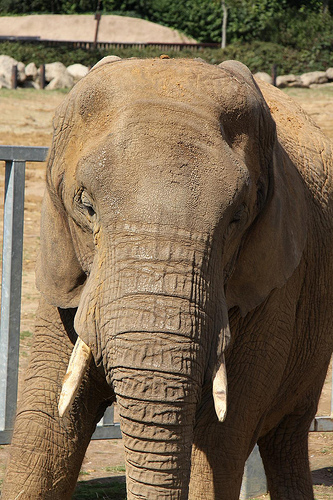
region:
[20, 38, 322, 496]
this is an elephant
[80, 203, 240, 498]
trunk of the elephant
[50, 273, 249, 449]
the elephant has tusks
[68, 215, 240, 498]
wrinkles on elephant trunk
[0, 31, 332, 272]
dirt on the elephant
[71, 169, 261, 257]
eyes on the elephant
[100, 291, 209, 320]
wrinkle on brown elephant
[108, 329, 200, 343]
wrinkle on brown elephant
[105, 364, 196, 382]
wrinkle on brown elephant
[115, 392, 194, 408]
wrinkle on brown elephant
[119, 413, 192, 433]
wrinkle on brown elephant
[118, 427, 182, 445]
wrinkle on brown elephant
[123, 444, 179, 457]
wrinkle on brown elephant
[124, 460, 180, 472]
wrinkle on brown elephant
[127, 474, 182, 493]
wrinkle on brown elephant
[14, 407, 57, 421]
wrinkle on brown elephant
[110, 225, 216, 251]
wrinkle on grey elephant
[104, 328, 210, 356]
wrinkle on grey elephant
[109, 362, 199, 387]
wrinkle on grey elephant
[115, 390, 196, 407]
wrinkle on grey elephant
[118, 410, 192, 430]
wrinkle on grey elephant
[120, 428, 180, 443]
wrinkle on grey elephant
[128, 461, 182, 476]
wrinkle on grey elephant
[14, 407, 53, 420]
wrinkle on grey elephant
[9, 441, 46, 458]
wrinkle on grey elephant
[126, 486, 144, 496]
wrinkle on grey elephant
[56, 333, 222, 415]
short tusks on an elephant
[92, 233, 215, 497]
wrinkled and creased trunk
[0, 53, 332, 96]
boulders on the edge of the enclosure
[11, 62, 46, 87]
two posts mounted by the the boulders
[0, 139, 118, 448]
metal gate behind the elephant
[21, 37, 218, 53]
a redwood colored railing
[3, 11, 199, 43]
a curved roofline on a building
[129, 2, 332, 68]
trees and bushes behind the building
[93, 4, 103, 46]
utility pole with a trandformer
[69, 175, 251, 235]
elephant eyes look down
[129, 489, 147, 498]
wrinkle on elephant trunk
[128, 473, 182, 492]
wrinkle on elephant trunk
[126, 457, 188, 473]
wrinkle on elephant trunk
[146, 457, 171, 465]
wrinkle on elephant trunk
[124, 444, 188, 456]
wrinkle on elephant trunk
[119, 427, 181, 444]
wrinkle on elephant trunk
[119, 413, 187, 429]
wrinkle on elephant trunk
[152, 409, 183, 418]
wrinkle on elephant trunk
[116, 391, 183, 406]
wrinkle on elephant trunk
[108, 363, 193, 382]
wrinkle on elephant trunk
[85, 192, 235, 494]
elephants trunk is wrinkled